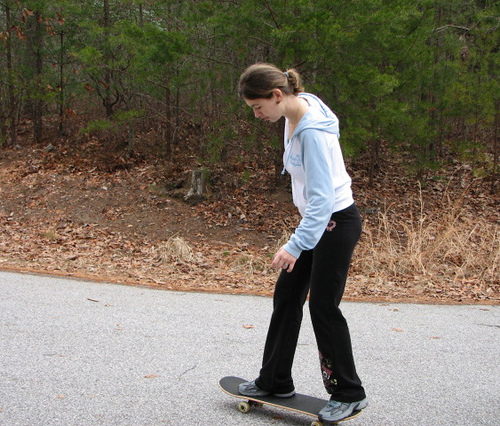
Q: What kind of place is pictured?
A: It is a forest.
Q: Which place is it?
A: It is a forest.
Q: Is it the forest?
A: Yes, it is the forest.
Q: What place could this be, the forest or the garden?
A: It is the forest.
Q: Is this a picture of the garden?
A: No, the picture is showing the forest.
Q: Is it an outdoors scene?
A: Yes, it is outdoors.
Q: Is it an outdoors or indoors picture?
A: It is outdoors.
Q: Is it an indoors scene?
A: No, it is outdoors.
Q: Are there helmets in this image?
A: No, there are no helmets.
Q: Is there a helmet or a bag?
A: No, there are no helmets or bags.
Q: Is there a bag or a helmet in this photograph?
A: No, there are no helmets or bags.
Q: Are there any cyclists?
A: No, there are no cyclists.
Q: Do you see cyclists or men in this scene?
A: No, there are no cyclists or men.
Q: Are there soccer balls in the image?
A: No, there are no soccer balls.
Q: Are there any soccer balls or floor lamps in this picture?
A: No, there are no soccer balls or floor lamps.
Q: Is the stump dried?
A: Yes, the stump is dried.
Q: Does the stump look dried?
A: Yes, the stump is dried.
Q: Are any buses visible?
A: No, there are no buses.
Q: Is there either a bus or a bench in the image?
A: No, there are no buses or benches.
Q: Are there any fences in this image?
A: No, there are no fences.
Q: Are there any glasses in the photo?
A: No, there are no glasses.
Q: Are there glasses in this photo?
A: No, there are no glasses.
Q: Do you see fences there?
A: No, there are no fences.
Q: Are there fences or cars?
A: No, there are no fences or cars.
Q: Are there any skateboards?
A: Yes, there is a skateboard.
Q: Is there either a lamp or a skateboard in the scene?
A: Yes, there is a skateboard.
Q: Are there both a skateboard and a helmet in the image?
A: No, there is a skateboard but no helmets.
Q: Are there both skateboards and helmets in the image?
A: No, there is a skateboard but no helmets.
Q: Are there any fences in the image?
A: No, there are no fences.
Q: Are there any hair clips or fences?
A: No, there are no fences or hair clips.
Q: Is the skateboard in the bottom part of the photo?
A: Yes, the skateboard is in the bottom of the image.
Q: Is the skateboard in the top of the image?
A: No, the skateboard is in the bottom of the image.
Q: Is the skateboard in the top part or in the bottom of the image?
A: The skateboard is in the bottom of the image.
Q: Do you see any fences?
A: No, there are no fences.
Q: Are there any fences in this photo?
A: No, there are no fences.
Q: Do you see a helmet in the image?
A: No, there are no helmets.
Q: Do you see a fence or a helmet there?
A: No, there are no helmets or fences.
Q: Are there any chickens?
A: No, there are no chickens.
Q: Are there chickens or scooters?
A: No, there are no chickens or scooters.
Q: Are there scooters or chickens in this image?
A: No, there are no chickens or scooters.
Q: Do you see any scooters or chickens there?
A: No, there are no chickens or scooters.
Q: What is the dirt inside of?
A: The dirt is inside the forest.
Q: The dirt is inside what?
A: The dirt is inside the forest.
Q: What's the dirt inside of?
A: The dirt is inside the forest.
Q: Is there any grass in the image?
A: Yes, there is grass.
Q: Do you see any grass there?
A: Yes, there is grass.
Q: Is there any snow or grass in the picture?
A: Yes, there is grass.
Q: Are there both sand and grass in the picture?
A: No, there is grass but no sand.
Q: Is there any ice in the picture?
A: No, there is no ice.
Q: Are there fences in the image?
A: No, there are no fences.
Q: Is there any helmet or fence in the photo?
A: No, there are no fences or helmets.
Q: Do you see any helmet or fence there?
A: No, there are no fences or helmets.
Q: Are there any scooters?
A: No, there are no scooters.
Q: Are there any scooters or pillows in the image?
A: No, there are no scooters or pillows.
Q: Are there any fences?
A: No, there are no fences.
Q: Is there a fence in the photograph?
A: No, there are no fences.